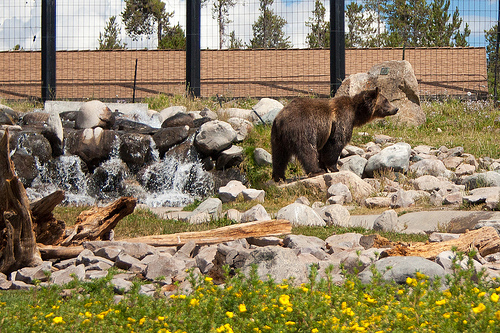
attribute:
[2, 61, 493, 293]
rocks — various sized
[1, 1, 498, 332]
cage — bear's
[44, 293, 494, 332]
flowers — yellow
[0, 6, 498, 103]
fence — black, metal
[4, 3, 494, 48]
sky — bright, blue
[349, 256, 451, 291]
rock — large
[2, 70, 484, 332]
field — small, green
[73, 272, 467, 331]
flower — yellow, buttercup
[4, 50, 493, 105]
wall — low, brick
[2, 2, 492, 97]
fence — metal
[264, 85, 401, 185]
bear — brown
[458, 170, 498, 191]
rock — large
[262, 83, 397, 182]
brown bear — large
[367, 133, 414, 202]
snowrock — large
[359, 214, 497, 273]
log — short, brown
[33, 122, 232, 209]
rock — large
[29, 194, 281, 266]
log — long, brown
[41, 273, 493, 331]
yellow flowers — small, Bright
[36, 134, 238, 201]
waterfall — small, stone